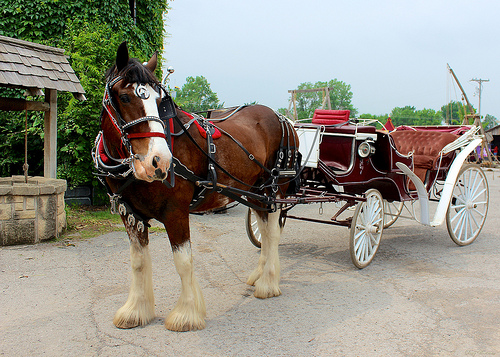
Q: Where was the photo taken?
A: It was taken at the sidewalk.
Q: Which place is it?
A: It is a sidewalk.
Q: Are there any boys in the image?
A: No, there are no boys.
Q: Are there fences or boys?
A: No, there are no boys or fences.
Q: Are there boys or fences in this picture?
A: No, there are no boys or fences.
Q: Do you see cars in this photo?
A: No, there are no cars.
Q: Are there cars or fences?
A: No, there are no cars or fences.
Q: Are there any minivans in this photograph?
A: No, there are no minivans.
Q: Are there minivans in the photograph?
A: No, there are no minivans.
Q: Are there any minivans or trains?
A: No, there are no minivans or trains.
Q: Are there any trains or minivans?
A: No, there are no minivans or trains.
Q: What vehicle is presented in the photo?
A: The vehicle is a wagon.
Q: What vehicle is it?
A: The vehicle is a wagon.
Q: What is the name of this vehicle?
A: This is a wagon.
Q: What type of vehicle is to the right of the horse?
A: The vehicle is a wagon.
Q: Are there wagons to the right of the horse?
A: Yes, there is a wagon to the right of the horse.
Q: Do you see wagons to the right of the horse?
A: Yes, there is a wagon to the right of the horse.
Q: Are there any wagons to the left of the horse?
A: No, the wagon is to the right of the horse.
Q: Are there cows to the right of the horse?
A: No, there is a wagon to the right of the horse.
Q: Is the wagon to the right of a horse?
A: Yes, the wagon is to the right of a horse.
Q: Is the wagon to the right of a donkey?
A: No, the wagon is to the right of a horse.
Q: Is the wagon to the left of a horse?
A: No, the wagon is to the right of a horse.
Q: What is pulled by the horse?
A: The wagon is pulled by the horse.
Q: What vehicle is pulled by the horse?
A: The vehicle is a wagon.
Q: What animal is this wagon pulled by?
A: The wagon is pulled by the horse.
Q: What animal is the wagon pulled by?
A: The wagon is pulled by the horse.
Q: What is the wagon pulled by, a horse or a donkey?
A: The wagon is pulled by a horse.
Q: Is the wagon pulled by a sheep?
A: No, the wagon is pulled by the horse.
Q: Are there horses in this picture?
A: Yes, there is a horse.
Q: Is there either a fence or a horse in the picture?
A: Yes, there is a horse.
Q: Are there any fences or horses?
A: Yes, there is a horse.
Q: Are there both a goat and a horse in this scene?
A: No, there is a horse but no goats.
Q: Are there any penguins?
A: No, there are no penguins.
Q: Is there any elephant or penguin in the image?
A: No, there are no penguins or elephants.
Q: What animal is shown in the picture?
A: The animal is a horse.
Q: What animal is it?
A: The animal is a horse.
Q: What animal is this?
A: This is a horse.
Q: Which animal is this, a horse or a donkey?
A: This is a horse.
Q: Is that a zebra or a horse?
A: That is a horse.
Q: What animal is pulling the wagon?
A: The horse is pulling the wagon.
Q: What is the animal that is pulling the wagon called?
A: The animal is a horse.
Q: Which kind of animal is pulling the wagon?
A: The animal is a horse.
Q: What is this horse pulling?
A: The horse is pulling the wagon.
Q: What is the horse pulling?
A: The horse is pulling the wagon.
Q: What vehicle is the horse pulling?
A: The horse is pulling the wagon.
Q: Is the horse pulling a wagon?
A: Yes, the horse is pulling a wagon.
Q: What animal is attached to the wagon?
A: The horse is attached to the wagon.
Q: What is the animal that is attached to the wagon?
A: The animal is a horse.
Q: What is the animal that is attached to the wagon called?
A: The animal is a horse.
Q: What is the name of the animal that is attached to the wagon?
A: The animal is a horse.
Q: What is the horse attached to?
A: The horse is attached to the wagon.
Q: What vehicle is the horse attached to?
A: The horse is attached to the wagon.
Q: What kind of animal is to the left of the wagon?
A: The animal is a horse.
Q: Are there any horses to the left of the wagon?
A: Yes, there is a horse to the left of the wagon.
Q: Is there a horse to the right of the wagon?
A: No, the horse is to the left of the wagon.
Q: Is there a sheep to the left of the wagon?
A: No, there is a horse to the left of the wagon.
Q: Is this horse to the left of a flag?
A: No, the horse is to the left of a wagon.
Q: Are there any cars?
A: No, there are no cars.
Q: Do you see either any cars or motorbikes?
A: No, there are no cars or motorbikes.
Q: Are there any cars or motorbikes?
A: No, there are no cars or motorbikes.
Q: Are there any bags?
A: No, there are no bags.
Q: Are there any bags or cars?
A: No, there are no bags or cars.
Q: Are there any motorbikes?
A: No, there are no motorbikes.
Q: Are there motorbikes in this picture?
A: No, there are no motorbikes.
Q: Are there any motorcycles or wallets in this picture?
A: No, there are no motorcycles or wallets.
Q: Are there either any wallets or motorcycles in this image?
A: No, there are no motorcycles or wallets.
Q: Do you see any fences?
A: No, there are no fences.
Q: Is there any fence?
A: No, there are no fences.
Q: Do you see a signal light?
A: No, there are no traffic lights.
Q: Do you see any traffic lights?
A: No, there are no traffic lights.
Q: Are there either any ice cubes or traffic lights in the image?
A: No, there are no traffic lights or ice cubes.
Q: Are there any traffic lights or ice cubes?
A: No, there are no traffic lights or ice cubes.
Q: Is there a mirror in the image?
A: No, there are no mirrors.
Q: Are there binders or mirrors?
A: No, there are no mirrors or binders.